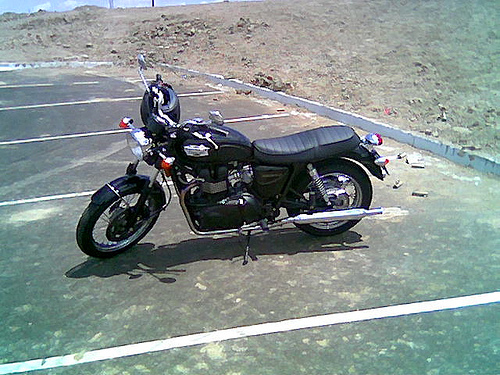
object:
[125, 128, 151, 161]
headlight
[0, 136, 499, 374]
spot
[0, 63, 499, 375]
lines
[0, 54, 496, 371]
lot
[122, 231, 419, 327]
no object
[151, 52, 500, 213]
curb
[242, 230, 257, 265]
kickstand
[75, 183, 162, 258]
front tire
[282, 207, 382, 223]
muffler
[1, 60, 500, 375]
pavement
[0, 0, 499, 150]
dirt patch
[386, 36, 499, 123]
dirt patch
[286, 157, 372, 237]
tire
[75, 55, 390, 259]
bike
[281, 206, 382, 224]
exhaust pipe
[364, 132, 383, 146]
light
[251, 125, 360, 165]
seat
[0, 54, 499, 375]
parking lot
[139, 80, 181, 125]
helmet